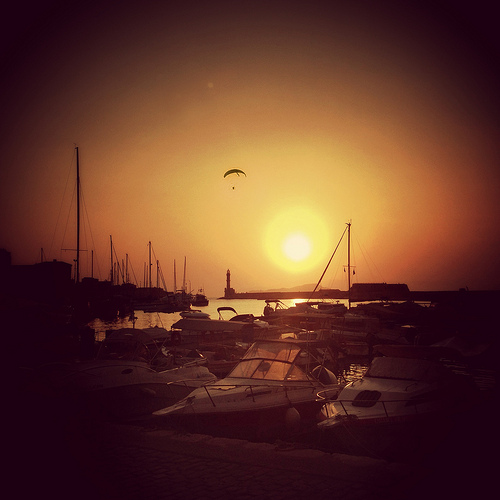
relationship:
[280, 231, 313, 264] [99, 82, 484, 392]
sun in sky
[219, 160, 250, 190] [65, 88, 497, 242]
bird in sky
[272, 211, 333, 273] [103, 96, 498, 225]
sun in sky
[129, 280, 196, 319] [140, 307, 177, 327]
boat in water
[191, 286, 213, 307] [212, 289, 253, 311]
boat in water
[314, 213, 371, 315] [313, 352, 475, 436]
silhouette by boat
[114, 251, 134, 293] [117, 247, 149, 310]
silhouette by ship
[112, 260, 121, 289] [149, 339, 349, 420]
silhouette by boat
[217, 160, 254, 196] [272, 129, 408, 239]
para sail in sky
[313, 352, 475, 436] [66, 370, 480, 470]
boat in dock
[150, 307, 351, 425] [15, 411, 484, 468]
boat in dock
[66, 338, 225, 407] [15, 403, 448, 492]
boat in dock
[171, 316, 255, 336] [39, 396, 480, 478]
boat in dock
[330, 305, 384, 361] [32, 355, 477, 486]
boat in dock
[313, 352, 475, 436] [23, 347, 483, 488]
boat in dock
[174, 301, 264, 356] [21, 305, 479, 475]
boat in dock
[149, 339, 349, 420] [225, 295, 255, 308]
boat on water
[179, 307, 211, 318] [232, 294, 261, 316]
boat on water water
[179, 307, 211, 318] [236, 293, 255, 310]
boat on water water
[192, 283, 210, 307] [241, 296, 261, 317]
boat on water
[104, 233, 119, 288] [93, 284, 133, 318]
mast by ship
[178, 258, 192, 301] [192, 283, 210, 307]
mast by boat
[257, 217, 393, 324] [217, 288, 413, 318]
boat on water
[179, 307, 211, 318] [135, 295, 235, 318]
boat on water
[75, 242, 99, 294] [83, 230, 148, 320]
mast by ship